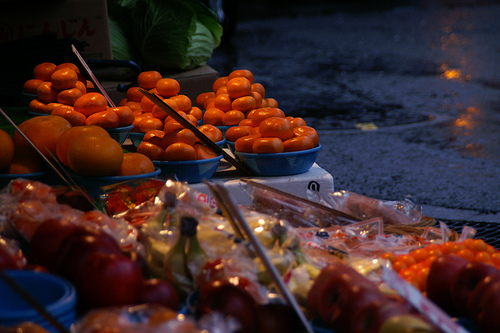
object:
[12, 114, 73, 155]
oranges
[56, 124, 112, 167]
tomato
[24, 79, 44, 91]
tomato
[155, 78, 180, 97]
this is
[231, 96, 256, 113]
this is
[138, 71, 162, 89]
we have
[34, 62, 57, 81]
this is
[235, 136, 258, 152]
tomato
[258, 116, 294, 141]
mandarin oranges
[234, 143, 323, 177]
blue bowl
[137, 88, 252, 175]
wooden stick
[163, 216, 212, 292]
bananas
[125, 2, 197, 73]
dark leaves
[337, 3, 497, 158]
reflection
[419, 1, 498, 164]
light on ground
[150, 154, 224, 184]
bowls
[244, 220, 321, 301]
yellow bananas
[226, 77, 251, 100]
oranges on table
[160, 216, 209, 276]
attached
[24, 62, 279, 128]
stacks of oranges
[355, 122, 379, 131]
metal grate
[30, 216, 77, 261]
tomatoes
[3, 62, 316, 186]
fruit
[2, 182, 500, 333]
fruit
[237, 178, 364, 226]
stick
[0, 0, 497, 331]
lights